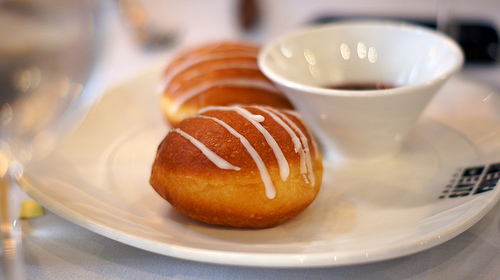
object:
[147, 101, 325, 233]
treat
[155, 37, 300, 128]
treat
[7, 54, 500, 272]
plate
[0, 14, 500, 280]
table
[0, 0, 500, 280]
ground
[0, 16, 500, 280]
white table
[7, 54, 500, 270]
dish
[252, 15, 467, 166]
bowl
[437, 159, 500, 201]
logo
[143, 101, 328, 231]
pastry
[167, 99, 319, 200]
frosting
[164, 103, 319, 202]
stripes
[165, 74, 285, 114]
stripes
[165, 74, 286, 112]
frosting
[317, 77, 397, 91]
compote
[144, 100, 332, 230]
doughnut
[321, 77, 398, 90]
liquid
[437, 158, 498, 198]
writing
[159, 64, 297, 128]
pastry